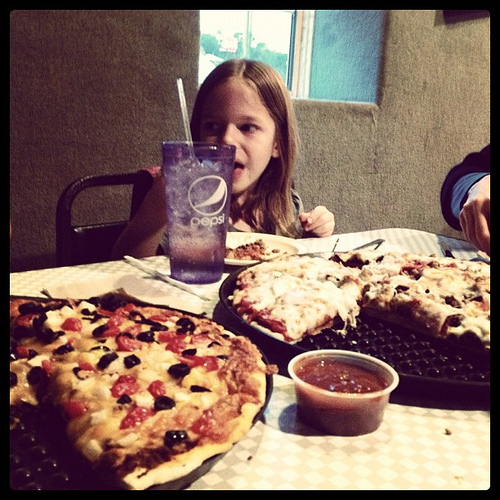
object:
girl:
[107, 53, 342, 261]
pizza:
[217, 234, 284, 263]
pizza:
[6, 301, 276, 490]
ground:
[388, 140, 438, 202]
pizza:
[11, 225, 499, 498]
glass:
[160, 142, 232, 285]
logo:
[187, 174, 227, 218]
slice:
[225, 238, 279, 259]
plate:
[188, 225, 303, 267]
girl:
[103, 48, 343, 270]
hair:
[189, 50, 300, 241]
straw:
[171, 68, 205, 190]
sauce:
[294, 356, 389, 436]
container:
[285, 347, 398, 437]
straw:
[163, 78, 197, 144]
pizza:
[9, 286, 279, 491]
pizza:
[224, 251, 491, 346]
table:
[0, 245, 497, 491]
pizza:
[64, 286, 264, 454]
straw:
[176, 90, 198, 135]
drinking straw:
[172, 74, 201, 163]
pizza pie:
[2, 276, 265, 490]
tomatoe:
[146, 378, 163, 394]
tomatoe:
[200, 355, 213, 367]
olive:
[124, 352, 140, 366]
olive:
[164, 426, 189, 444]